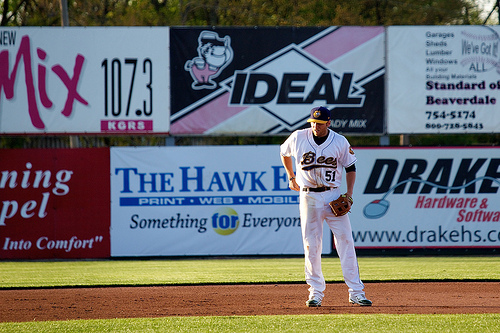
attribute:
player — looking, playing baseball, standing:
[278, 106, 375, 309]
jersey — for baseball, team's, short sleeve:
[276, 124, 361, 189]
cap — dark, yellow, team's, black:
[303, 108, 336, 123]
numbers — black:
[98, 57, 157, 115]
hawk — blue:
[113, 163, 268, 196]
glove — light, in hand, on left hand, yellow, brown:
[330, 193, 358, 218]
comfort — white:
[38, 237, 97, 249]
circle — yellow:
[212, 208, 238, 237]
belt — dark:
[303, 186, 336, 193]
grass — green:
[4, 256, 500, 287]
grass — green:
[18, 315, 486, 332]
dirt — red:
[5, 285, 499, 312]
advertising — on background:
[7, 29, 499, 254]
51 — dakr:
[327, 167, 335, 184]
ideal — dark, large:
[230, 72, 366, 108]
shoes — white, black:
[347, 289, 377, 308]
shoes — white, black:
[304, 292, 320, 310]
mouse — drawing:
[364, 193, 391, 220]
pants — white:
[298, 191, 367, 291]